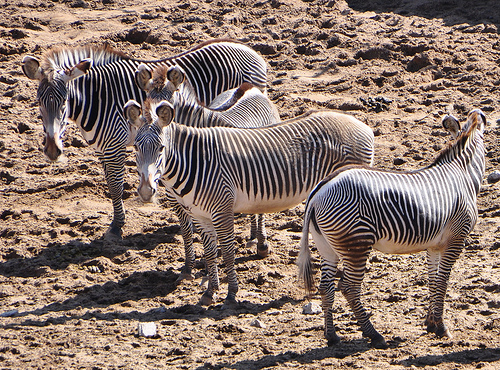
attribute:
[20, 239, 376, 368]
dirt — packed, tan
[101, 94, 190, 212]
face — zebra's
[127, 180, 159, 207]
nose — white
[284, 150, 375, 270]
back end — zebra's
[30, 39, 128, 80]
mane — zebra's, standing up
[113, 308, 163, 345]
rock — white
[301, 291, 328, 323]
rock — white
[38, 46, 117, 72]
mane — black, white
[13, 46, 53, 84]
ear — white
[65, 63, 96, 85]
ear — white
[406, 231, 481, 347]
legs — white, black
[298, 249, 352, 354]
legs — black, white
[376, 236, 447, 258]
belly — white, dirty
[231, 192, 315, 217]
belly — dirty, white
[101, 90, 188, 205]
head — zebra's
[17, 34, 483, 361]
zebra — adult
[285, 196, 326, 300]
tail — white 